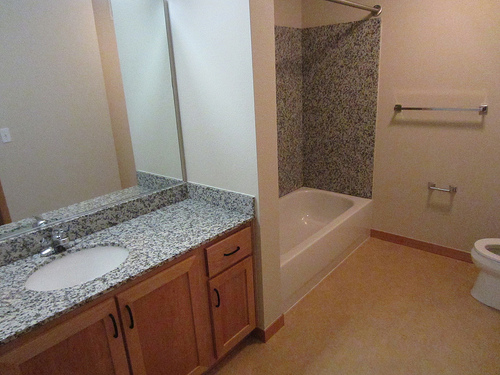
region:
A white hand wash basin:
[67, 255, 97, 273]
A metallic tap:
[52, 231, 64, 246]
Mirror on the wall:
[46, 118, 93, 189]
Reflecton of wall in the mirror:
[131, 40, 163, 116]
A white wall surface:
[190, 32, 240, 159]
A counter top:
[144, 223, 186, 246]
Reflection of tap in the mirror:
[35, 216, 45, 224]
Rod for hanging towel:
[416, 109, 465, 111]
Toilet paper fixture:
[432, 189, 449, 191]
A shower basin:
[286, 213, 310, 232]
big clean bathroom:
[0, 3, 496, 360]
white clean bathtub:
[264, 185, 374, 301]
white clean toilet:
[469, 238, 498, 301]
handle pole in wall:
[393, 100, 490, 113]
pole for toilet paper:
[426, 180, 458, 199]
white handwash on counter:
[22, 235, 124, 300]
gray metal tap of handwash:
[40, 227, 68, 266]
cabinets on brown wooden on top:
[0, 221, 260, 373]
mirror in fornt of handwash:
[0, 0, 184, 252]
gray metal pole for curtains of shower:
[280, 0, 380, 16]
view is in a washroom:
[101, 50, 461, 365]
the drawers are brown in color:
[109, 263, 254, 347]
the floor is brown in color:
[315, 294, 499, 370]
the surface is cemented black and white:
[147, 190, 216, 249]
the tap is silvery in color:
[39, 220, 71, 247]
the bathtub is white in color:
[291, 166, 351, 258]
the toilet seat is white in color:
[461, 243, 498, 304]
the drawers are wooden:
[167, 294, 252, 344]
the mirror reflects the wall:
[56, 81, 137, 170]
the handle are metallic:
[394, 98, 495, 121]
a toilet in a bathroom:
[459, 228, 499, 313]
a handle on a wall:
[391, 96, 497, 119]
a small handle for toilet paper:
[424, 175, 459, 196]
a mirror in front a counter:
[3, 5, 188, 242]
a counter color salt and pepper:
[7, 186, 242, 305]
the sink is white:
[16, 240, 128, 295]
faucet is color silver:
[30, 215, 75, 261]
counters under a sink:
[69, 229, 259, 374]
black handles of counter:
[106, 303, 138, 343]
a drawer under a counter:
[197, 219, 261, 280]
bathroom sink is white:
[22, 241, 134, 295]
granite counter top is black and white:
[0, 178, 254, 343]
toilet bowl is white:
[469, 233, 499, 315]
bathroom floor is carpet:
[194, 240, 498, 374]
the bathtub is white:
[278, 185, 373, 314]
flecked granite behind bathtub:
[276, 17, 381, 205]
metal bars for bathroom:
[325, 0, 492, 195]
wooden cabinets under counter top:
[0, 224, 259, 374]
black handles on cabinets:
[108, 245, 243, 337]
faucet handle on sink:
[33, 218, 76, 258]